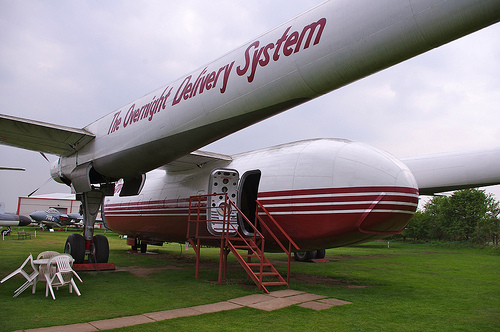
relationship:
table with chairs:
[32, 257, 75, 294] [8, 246, 84, 304]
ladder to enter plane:
[186, 189, 300, 295] [86, 52, 421, 274]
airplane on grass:
[0, 0, 499, 262] [4, 222, 498, 328]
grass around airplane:
[4, 222, 498, 328] [0, 0, 499, 262]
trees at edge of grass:
[406, 184, 498, 254] [4, 222, 498, 328]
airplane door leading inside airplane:
[206, 166, 243, 235] [0, 0, 499, 262]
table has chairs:
[27, 253, 77, 295] [1, 249, 85, 304]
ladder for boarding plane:
[208, 190, 312, 297] [76, 64, 467, 294]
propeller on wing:
[25, 152, 82, 201] [0, 109, 92, 156]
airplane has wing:
[0, 0, 499, 262] [0, 109, 92, 156]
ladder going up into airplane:
[186, 189, 300, 295] [0, 0, 499, 262]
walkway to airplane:
[140, 295, 321, 315] [0, 0, 499, 262]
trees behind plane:
[406, 184, 498, 254] [31, 102, 415, 256]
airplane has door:
[0, 0, 499, 262] [211, 168, 241, 235]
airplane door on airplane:
[206, 163, 243, 235] [2, 124, 499, 275]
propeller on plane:
[0, 152, 66, 197] [0, 32, 496, 283]